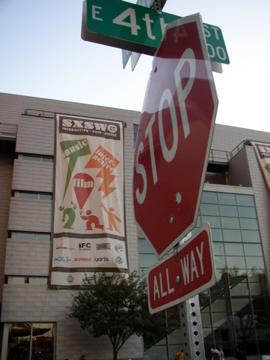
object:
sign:
[146, 221, 216, 314]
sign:
[131, 12, 219, 261]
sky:
[0, 0, 270, 134]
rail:
[23, 107, 127, 129]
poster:
[248, 141, 269, 192]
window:
[234, 193, 256, 207]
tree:
[64, 268, 151, 359]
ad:
[46, 112, 131, 289]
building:
[0, 92, 270, 359]